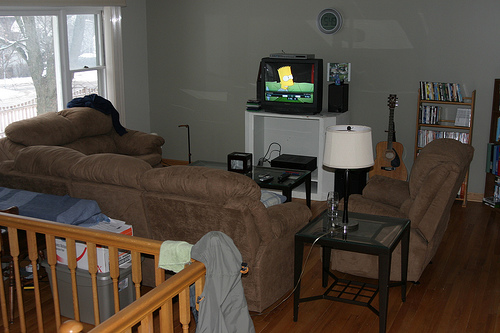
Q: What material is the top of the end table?
A: Glass.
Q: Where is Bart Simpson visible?
A: TV on mantle.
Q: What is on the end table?
A: Lamp.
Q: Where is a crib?
A: Behind sofa.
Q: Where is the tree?
A: Outside window.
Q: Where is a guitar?
A: Right of mantle.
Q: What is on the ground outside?
A: Snow.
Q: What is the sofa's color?
A: Brown.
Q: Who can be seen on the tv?
A: Bart Simpson.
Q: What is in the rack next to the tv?
A: DVDs.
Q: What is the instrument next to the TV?
A: Guitar.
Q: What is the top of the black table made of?
A: Glass.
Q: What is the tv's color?
A: Black.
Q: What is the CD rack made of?
A: Wood.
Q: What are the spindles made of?
A: Wood.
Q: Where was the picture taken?
A: In a living room.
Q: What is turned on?
A: TV screen.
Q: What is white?
A: Lampshade.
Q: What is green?
A: Blanket.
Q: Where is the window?
A: To the left.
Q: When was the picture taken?
A: Daytime.